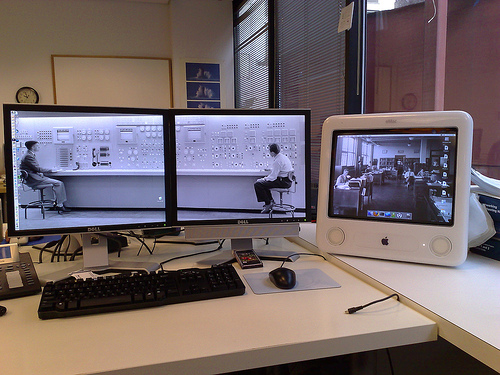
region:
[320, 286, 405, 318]
small black power cord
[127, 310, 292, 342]
shiny white desk surface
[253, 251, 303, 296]
black mouse on pad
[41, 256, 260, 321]
black computer key board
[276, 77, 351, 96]
white blinds in the back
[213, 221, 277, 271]
silver base on computer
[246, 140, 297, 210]
man sitting on stool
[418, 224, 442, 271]
white knob on front of the screen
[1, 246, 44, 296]
gray land line telephone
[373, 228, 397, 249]
small black logo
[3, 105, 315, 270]
dual computer monitors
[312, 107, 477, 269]
apple computer monitor on desk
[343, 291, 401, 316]
unplugged phone charger in between two desks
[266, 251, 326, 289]
computer mouse on a mousepad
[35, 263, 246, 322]
keyboard on the desk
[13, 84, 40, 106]
clock on the wall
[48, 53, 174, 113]
marker board on the wall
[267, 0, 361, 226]
window with its blinds closed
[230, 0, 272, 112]
window with the blinds partially open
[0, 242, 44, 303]
telephone system off to the side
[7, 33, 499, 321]
three monitors on a desk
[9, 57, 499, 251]
three monitors on a table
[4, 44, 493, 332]
three monitors turned on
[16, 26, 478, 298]
three computer monitors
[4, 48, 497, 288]
three computer monitors on a table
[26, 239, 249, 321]
a black keyboard on a table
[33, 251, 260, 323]
a black computer keyboard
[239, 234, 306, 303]
a computer black mouse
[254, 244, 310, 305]
a computer mouse on a table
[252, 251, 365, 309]
a mouse pad on a table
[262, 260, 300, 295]
computer mouse on mousepad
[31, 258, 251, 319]
black keyboard on desk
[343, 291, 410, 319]
cord with nothing attached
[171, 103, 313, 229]
computer screen with picture in it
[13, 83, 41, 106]
clock on wall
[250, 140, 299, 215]
man sitting on stool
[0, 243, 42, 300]
phone with buttons on it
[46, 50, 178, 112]
cleared whiteboard on wall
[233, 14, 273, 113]
slightly opened blinds on window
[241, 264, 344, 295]
gray mousepad with mouse on it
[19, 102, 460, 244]
three computer screens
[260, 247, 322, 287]
black mouse with cord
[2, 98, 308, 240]
side by side computer screens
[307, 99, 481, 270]
white apple monitor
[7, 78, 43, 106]
white and black clock on the wall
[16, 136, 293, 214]
people pictured sitting on the computer screens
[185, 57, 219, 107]
blue and white posters on the wall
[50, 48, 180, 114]
whiteboard on the wall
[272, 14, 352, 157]
blinds covering over window